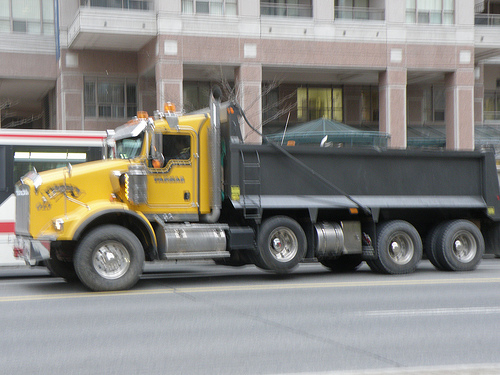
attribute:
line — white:
[282, 287, 499, 373]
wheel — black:
[72, 222, 142, 290]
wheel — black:
[255, 209, 307, 274]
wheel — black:
[367, 214, 422, 272]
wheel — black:
[435, 212, 485, 271]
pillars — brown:
[156, 22, 487, 148]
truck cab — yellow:
[19, 105, 227, 282]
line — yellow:
[0, 274, 500, 304]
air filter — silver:
[128, 167, 143, 200]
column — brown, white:
[152, 35, 184, 117]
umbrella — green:
[261, 113, 388, 147]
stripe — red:
[4, 124, 108, 146]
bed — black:
[236, 141, 499, 218]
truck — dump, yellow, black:
[26, 103, 493, 277]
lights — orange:
[129, 86, 219, 123]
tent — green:
[264, 114, 389, 138]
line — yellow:
[2, 274, 484, 323]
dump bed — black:
[215, 134, 495, 218]